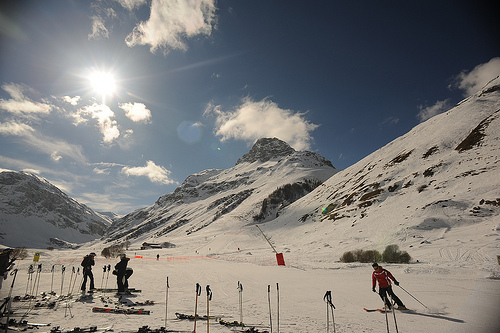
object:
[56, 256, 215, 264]
boundaries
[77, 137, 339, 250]
mountain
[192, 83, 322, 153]
white cloud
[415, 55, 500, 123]
white cloud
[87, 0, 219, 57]
white cloud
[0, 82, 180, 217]
white clouds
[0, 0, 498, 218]
blue sky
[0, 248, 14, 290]
person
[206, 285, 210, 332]
poles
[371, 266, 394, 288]
coat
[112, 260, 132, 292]
coat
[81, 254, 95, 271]
coat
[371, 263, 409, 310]
people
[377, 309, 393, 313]
ski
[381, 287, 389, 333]
poles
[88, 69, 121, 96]
bright sun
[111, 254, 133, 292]
people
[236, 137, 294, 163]
mountaintops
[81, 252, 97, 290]
man walking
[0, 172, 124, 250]
mountain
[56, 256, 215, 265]
fence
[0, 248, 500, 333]
ground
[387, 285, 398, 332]
poles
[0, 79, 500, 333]
snow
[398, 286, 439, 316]
poles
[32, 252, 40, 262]
sign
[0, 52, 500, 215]
day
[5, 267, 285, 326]
ski poles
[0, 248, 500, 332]
tracks